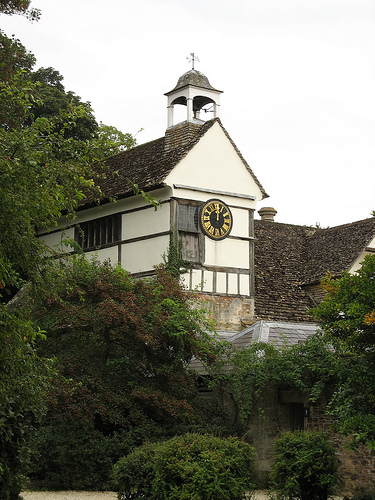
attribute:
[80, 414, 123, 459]
leaves — green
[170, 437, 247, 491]
leaves — green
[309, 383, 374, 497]
wall — rock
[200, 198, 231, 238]
clock — black and white, round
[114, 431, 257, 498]
bush — brown